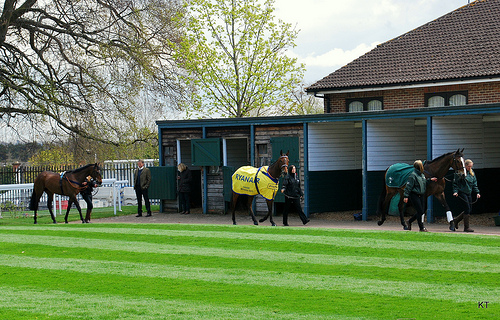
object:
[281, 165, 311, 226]
person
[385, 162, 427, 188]
cover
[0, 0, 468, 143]
sky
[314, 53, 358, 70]
clouds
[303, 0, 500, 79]
roof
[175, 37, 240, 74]
leaves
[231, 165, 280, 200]
cover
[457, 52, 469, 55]
tile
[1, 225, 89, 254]
grass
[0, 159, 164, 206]
fence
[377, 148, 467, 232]
horse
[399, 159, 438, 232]
people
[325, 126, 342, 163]
wall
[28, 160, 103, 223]
brown horse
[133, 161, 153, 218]
men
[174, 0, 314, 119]
tree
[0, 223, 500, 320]
grass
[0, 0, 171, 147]
tree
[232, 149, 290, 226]
brown horse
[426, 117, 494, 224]
dividers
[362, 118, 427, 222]
dividers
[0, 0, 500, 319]
picture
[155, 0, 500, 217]
building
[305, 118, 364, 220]
stables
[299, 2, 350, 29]
clouds